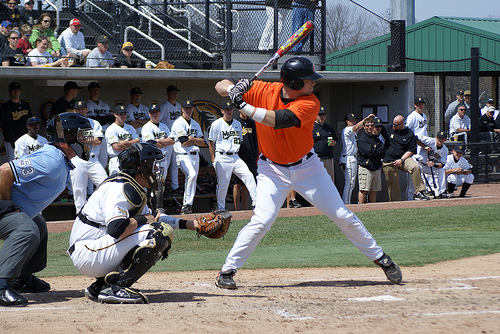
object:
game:
[15, 62, 497, 305]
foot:
[214, 269, 241, 292]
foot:
[375, 249, 404, 285]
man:
[0, 110, 94, 308]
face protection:
[71, 124, 98, 161]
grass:
[393, 208, 483, 254]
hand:
[184, 214, 223, 237]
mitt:
[196, 210, 233, 241]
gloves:
[224, 85, 249, 109]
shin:
[112, 227, 171, 292]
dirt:
[281, 294, 425, 333]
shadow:
[243, 279, 400, 288]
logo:
[382, 257, 391, 265]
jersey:
[6, 144, 76, 221]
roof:
[326, 16, 499, 56]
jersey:
[225, 78, 322, 166]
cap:
[69, 17, 83, 27]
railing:
[123, 25, 168, 68]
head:
[390, 114, 404, 133]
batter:
[213, 54, 406, 290]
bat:
[219, 19, 318, 111]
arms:
[188, 135, 209, 149]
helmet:
[117, 143, 170, 192]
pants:
[220, 149, 385, 277]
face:
[149, 159, 167, 189]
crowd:
[0, 12, 141, 69]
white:
[93, 187, 120, 215]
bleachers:
[0, 0, 322, 72]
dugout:
[3, 79, 410, 219]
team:
[3, 81, 474, 216]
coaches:
[356, 112, 390, 204]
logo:
[221, 130, 242, 145]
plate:
[344, 293, 407, 304]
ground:
[293, 280, 493, 319]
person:
[65, 143, 235, 306]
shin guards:
[105, 245, 163, 291]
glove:
[195, 208, 234, 239]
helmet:
[278, 56, 323, 93]